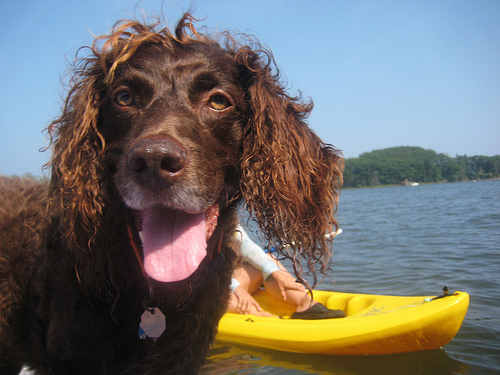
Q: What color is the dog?
A: Brown.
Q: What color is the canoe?
A: Yellow.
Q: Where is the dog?
A: On the water.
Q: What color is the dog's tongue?
A: Pink.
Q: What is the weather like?
A: Sunny.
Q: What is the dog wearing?
A: A collar and tags.